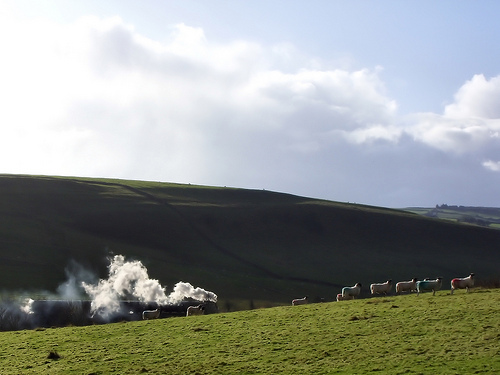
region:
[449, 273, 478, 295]
a white standing sheep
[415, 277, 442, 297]
a white standing sheep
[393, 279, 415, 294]
a white standing sheep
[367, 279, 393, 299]
a white standing sheep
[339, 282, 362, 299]
a white standing sheep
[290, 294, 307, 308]
a white standing sheep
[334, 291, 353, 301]
a white standing sheep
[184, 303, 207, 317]
a white standing sheep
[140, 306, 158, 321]
a white standing sheep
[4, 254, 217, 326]
a plume of smoke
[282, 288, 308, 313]
sheep in the field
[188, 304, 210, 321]
sheep in the field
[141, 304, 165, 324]
sheep in the field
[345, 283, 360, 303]
sheep in the field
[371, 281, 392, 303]
sheep in the field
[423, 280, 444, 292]
sheep in the field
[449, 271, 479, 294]
sheep in the field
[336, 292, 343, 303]
sheep in the field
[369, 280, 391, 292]
sheep in the field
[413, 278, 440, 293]
sheep in the field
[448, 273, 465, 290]
the sheep has a red marking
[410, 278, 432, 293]
the sheep has a blue marking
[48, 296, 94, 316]
the train is black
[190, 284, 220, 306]
the steam is gray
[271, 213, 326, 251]
the hillside is green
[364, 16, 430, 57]
the sky is blue in color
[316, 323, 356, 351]
the grass is green in color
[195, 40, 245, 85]
the clouds are white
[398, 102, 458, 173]
the clouds are fluffy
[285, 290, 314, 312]
the sheep is white and black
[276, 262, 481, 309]
herd of sheep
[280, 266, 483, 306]
sheep standing on the grass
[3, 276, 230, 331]
black train on the tracks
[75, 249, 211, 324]
thick whtie steam coming off the train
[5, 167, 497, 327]
hill covered in grass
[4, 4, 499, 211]
thick white clouds in the sky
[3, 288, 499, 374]
bright green grass on the ground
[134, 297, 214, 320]
two sheep on the grass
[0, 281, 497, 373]
ground is slightly sloped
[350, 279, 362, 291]
small black head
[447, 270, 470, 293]
Red butt on animal.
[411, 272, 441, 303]
Blue butt on animal.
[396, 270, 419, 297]
White animal standing in field.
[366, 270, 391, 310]
White animal standing in field.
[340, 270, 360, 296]
Animal has blue butt.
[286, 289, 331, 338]
White animal standing in field.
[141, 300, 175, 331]
White animal standing in grassy field.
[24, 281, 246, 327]
Black train behind animals.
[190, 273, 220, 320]
Smoke coming out of train.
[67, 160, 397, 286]
Grassy hillside in distance.